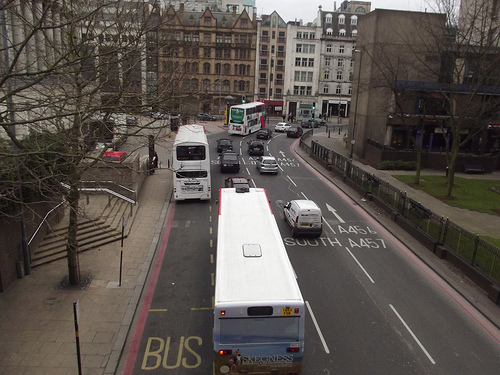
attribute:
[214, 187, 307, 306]
roof — white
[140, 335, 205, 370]
bus — printed, yellow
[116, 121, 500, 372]
street — curving to right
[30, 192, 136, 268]
steps — paved, shallow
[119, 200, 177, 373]
stripe — red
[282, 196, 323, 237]
van — white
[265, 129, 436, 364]
line — white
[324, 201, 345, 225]
arrow — white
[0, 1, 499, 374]
photo — from above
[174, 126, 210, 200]
bus — waiting, parked, white, two story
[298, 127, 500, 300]
fence — brown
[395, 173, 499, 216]
grass — green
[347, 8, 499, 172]
building — brown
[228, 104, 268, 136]
bus — white, red, double decker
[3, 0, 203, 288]
tree — leafless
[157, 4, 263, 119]
building — tall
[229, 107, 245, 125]
bus back — green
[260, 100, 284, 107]
awning — red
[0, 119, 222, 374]
sidewalk — paved